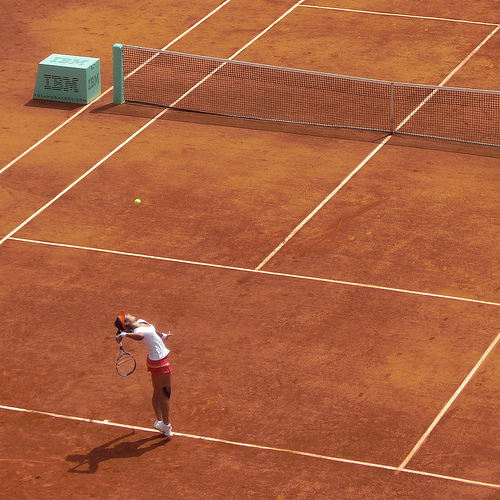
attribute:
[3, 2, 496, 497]
field — tennis, brown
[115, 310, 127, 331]
visor — orange, tennis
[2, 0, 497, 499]
tennis field — brown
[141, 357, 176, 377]
skirt — pink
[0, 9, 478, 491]
tennis court — brown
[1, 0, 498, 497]
court — brown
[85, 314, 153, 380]
racket — blue, tennis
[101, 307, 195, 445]
she — playing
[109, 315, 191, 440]
lady — stretching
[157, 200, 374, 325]
court — stripped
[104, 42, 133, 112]
pole — teal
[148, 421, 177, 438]
shoes — white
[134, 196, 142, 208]
ball — small, tennis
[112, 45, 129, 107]
net frame — green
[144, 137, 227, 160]
wall — white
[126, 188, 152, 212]
ball — tennis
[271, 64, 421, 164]
net — white, black, tennis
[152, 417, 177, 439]
shoes — tennis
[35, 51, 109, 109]
box — green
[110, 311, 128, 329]
visor — red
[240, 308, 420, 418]
floor — brown